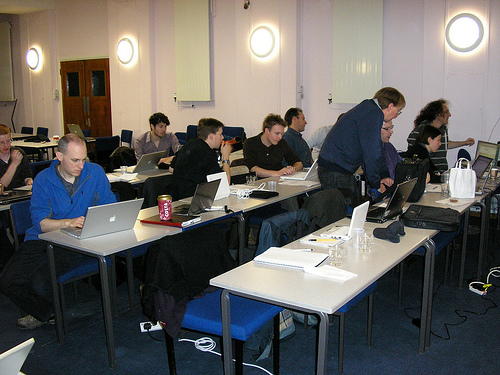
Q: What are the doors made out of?
A: Wood.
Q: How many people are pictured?
A: Ten.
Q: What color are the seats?
A: Blue.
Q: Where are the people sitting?
A: At desks.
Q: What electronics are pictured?
A: Laptops.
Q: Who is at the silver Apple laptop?
A: The man in the blue shirt.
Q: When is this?
A: Night time.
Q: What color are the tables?
A: White.